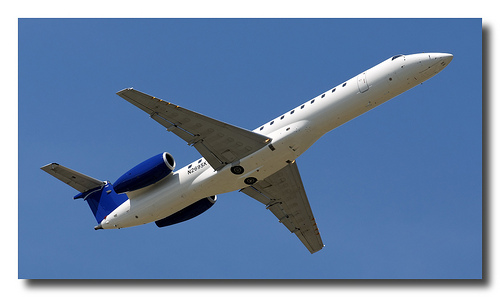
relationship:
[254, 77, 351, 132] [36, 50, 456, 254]
windows on airplane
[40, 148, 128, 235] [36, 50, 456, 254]
wing on airplane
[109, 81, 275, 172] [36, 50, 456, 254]
wings on airplane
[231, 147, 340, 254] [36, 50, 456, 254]
wing on airplane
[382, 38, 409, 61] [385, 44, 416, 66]
cockpit windshield on cockpit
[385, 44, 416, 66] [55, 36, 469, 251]
cockpit on jet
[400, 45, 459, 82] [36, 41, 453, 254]
nose on airplane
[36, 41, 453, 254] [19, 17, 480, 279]
airplane in sky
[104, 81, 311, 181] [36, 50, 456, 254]
wings on airplane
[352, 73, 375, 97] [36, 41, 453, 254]
door of airplane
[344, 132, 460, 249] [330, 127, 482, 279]
clouds of sky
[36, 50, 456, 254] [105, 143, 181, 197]
airplane has engine